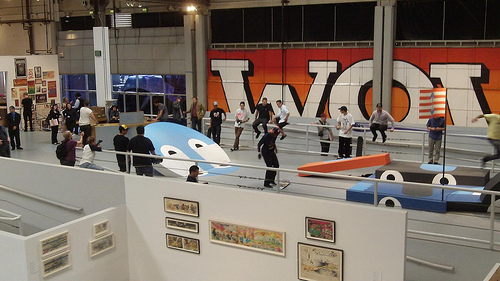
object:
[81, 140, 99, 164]
shirt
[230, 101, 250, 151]
person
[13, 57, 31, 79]
pictures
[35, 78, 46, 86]
pictures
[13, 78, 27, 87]
pictures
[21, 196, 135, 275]
partition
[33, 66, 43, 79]
picture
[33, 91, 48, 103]
picture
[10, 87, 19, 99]
picture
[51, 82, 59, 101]
picture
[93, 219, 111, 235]
picture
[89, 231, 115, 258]
picture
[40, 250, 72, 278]
picture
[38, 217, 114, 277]
picture frames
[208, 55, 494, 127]
lettering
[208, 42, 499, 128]
wall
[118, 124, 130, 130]
hat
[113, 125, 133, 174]
person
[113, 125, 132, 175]
man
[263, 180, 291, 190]
skateboard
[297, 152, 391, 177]
orange ramp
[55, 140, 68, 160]
backpack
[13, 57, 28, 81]
picture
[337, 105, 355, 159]
person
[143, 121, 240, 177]
object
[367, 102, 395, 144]
boys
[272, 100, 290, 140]
boys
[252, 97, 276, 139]
boys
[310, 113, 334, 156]
boys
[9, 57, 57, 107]
signs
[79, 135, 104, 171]
people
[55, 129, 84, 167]
people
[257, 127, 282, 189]
man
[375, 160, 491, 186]
black block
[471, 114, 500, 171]
man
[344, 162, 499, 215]
objects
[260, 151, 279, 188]
black pants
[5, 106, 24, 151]
man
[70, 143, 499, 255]
railing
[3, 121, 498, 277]
floor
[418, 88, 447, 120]
flag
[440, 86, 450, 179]
pole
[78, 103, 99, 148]
man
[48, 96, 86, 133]
shirt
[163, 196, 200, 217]
picture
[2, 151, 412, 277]
wall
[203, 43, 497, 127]
coloring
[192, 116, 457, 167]
railing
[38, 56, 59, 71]
wall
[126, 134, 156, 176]
suit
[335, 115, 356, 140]
shirt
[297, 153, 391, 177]
block